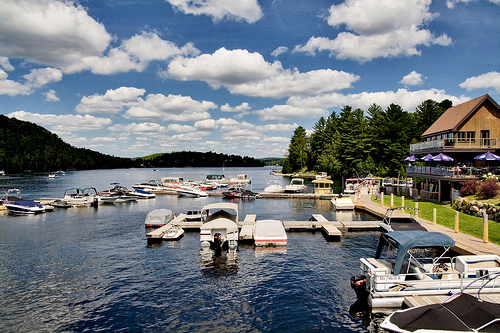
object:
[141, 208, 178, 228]
ship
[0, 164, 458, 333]
water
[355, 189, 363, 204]
people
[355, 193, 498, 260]
boardwalk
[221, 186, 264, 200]
boat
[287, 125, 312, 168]
tree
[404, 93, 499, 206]
house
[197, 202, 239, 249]
boat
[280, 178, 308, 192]
boat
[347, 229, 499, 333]
boat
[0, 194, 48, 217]
boat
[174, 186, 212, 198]
boat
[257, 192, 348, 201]
dock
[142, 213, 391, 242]
dock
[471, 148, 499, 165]
umbrella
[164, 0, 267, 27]
cloud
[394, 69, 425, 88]
cloud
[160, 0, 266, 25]
cloud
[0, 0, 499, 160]
sky